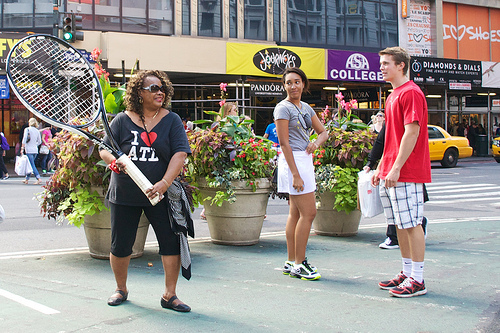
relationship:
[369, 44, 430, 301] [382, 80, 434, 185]
man wearing shirt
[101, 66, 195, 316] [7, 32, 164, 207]
woman carrying racket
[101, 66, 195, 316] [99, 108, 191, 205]
woman wearing i <3 atl shirt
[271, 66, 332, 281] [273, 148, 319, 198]
woman wearing skirt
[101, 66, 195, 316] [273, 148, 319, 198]
woman wearing skirt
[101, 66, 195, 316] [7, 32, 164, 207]
woman holding racket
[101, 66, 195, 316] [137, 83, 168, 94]
woman wearing sunglasses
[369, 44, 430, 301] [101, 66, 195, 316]
man sees woman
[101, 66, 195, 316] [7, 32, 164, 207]
woman holds racket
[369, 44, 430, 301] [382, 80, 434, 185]
man wears shirt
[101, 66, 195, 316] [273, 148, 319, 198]
woman wears skirt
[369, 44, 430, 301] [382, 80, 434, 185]
man in shirt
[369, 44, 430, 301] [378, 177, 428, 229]
man wearing shorts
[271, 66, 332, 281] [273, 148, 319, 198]
woman in skirt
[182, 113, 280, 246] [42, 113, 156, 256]
pot of flowers next to flower pot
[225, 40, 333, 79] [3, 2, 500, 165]
journeys banner on building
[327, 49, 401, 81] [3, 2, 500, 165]
asa college banner on building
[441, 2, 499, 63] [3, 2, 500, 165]
i <3 shoes banner on building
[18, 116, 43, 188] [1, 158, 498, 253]
person walking on street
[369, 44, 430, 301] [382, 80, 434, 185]
man has shirt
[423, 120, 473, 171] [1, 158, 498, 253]
cab parked on side of street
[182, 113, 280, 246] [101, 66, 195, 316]
pot of flowers next to woman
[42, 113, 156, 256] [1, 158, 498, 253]
flower pot next to street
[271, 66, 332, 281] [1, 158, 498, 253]
woman next to street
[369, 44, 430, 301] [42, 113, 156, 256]
man next to flower pot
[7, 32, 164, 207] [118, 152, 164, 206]
racket has handle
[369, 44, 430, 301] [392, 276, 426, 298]
man has shoe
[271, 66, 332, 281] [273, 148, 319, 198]
woman has skirt